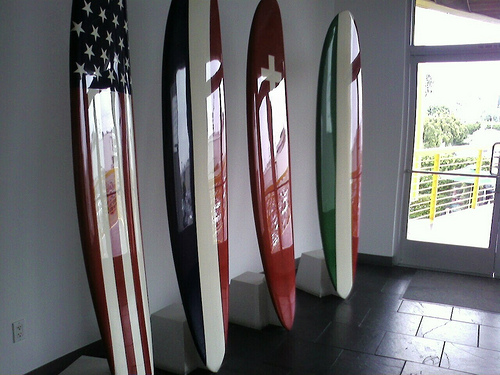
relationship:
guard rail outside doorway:
[406, 142, 498, 222] [389, 49, 499, 279]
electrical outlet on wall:
[11, 316, 26, 343] [1, 1, 333, 372]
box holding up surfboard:
[221, 266, 294, 338] [242, 0, 304, 332]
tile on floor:
[361, 273, 412, 299] [306, 254, 489, 373]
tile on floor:
[351, 287, 403, 314] [229, 261, 499, 373]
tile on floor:
[412, 313, 480, 350] [110, 265, 498, 374]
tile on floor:
[447, 306, 498, 347] [364, 245, 412, 373]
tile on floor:
[473, 307, 498, 349] [88, 281, 493, 372]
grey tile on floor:
[369, 332, 454, 367] [39, 252, 499, 370]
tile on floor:
[356, 301, 418, 336] [173, 265, 498, 374]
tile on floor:
[412, 313, 480, 350] [173, 265, 498, 374]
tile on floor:
[437, 339, 499, 374] [173, 265, 498, 374]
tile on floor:
[268, 335, 342, 370] [173, 265, 498, 374]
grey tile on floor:
[380, 332, 455, 362] [39, 252, 499, 370]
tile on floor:
[316, 322, 387, 354] [60, 266, 497, 372]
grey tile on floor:
[369, 332, 454, 367] [60, 266, 497, 372]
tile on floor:
[437, 339, 499, 374] [60, 266, 497, 372]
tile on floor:
[412, 313, 480, 350] [60, 266, 497, 372]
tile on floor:
[358, 307, 422, 333] [60, 266, 497, 372]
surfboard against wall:
[158, 1, 241, 372] [4, 1, 368, 371]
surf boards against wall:
[241, 0, 299, 333] [4, 1, 368, 371]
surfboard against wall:
[313, 5, 362, 300] [4, 1, 368, 371]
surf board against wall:
[64, 0, 156, 375] [4, 1, 368, 371]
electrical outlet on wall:
[11, 316, 26, 343] [22, 194, 82, 324]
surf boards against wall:
[56, 4, 383, 374] [2, 3, 379, 339]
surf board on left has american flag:
[64, 0, 156, 375] [66, 0, 155, 374]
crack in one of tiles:
[420, 317, 447, 337] [155, 265, 493, 373]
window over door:
[408, 0, 498, 48] [406, 56, 499, 256]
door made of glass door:
[400, 60, 497, 274] [412, 47, 496, 249]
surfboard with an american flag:
[313, 5, 362, 300] [73, 0, 153, 374]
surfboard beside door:
[313, 5, 360, 300] [407, 57, 495, 277]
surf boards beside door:
[241, 0, 299, 333] [407, 57, 495, 277]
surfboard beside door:
[158, 1, 235, 372] [407, 57, 495, 277]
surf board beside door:
[64, 0, 156, 375] [407, 57, 495, 277]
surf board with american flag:
[64, 0, 156, 375] [73, 0, 153, 374]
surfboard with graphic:
[313, 5, 362, 300] [320, 17, 358, 295]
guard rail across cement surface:
[406, 142, 498, 222] [421, 204, 486, 240]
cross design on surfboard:
[251, 51, 289, 97] [32, 24, 159, 373]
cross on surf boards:
[256, 56, 286, 97] [241, 0, 299, 333]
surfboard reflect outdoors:
[158, 1, 235, 372] [411, 74, 495, 264]